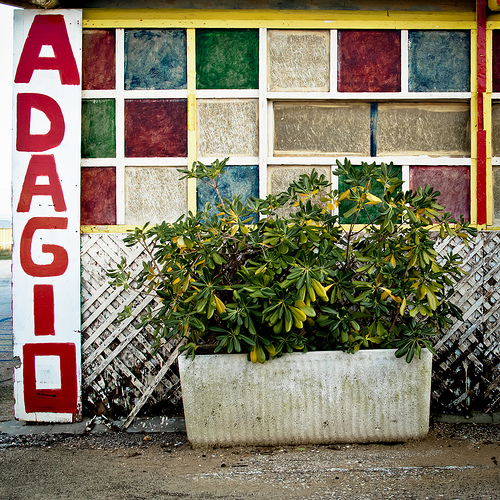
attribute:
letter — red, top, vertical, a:
[12, 13, 82, 87]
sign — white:
[11, 8, 86, 423]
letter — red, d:
[15, 93, 65, 153]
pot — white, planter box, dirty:
[176, 346, 434, 449]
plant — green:
[106, 156, 479, 365]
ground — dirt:
[2, 422, 499, 499]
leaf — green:
[285, 268, 304, 281]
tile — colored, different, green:
[195, 27, 261, 91]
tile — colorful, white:
[195, 97, 259, 159]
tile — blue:
[123, 27, 188, 91]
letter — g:
[19, 217, 68, 279]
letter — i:
[32, 284, 56, 337]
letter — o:
[22, 341, 77, 415]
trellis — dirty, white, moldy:
[82, 230, 499, 416]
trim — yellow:
[81, 9, 478, 234]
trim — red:
[478, 1, 488, 225]